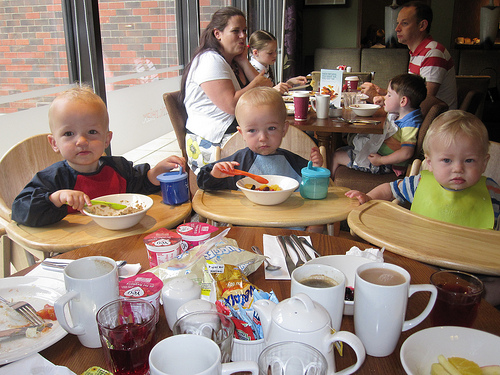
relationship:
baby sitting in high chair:
[10, 81, 189, 231] [0, 129, 193, 256]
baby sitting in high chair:
[193, 88, 324, 207] [194, 119, 364, 227]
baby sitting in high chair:
[344, 108, 499, 232] [348, 134, 497, 274]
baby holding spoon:
[193, 88, 324, 207] [213, 165, 274, 184]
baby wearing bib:
[344, 108, 499, 232] [405, 167, 496, 234]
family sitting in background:
[160, 2, 461, 188] [2, 0, 493, 131]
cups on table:
[51, 239, 440, 373] [2, 223, 494, 373]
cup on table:
[52, 251, 119, 351] [2, 223, 494, 373]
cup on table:
[287, 257, 348, 339] [2, 223, 494, 373]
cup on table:
[352, 262, 437, 358] [2, 223, 494, 373]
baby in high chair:
[10, 81, 189, 231] [0, 129, 193, 256]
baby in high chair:
[193, 88, 324, 207] [194, 119, 364, 227]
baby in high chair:
[344, 108, 499, 232] [348, 134, 497, 274]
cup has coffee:
[287, 257, 348, 339] [297, 274, 337, 288]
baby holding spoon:
[193, 88, 324, 207] [218, 166, 271, 186]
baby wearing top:
[10, 81, 189, 231] [11, 153, 152, 232]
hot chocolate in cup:
[362, 263, 402, 285] [352, 256, 438, 358]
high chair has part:
[194, 119, 364, 227] [195, 185, 350, 227]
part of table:
[333, 115, 347, 131] [267, 55, 411, 146]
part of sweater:
[192, 96, 215, 123] [177, 45, 248, 147]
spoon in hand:
[221, 159, 279, 190] [214, 154, 244, 187]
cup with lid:
[300, 163, 331, 201] [302, 157, 332, 181]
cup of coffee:
[350, 255, 437, 371] [364, 264, 399, 285]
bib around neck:
[404, 165, 497, 240] [416, 174, 487, 203]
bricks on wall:
[123, 19, 155, 57] [5, 5, 235, 141]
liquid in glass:
[106, 332, 143, 367] [92, 294, 161, 371]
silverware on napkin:
[268, 224, 328, 277] [255, 226, 325, 289]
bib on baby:
[409, 165, 495, 231] [344, 107, 499, 242]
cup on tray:
[295, 163, 345, 204] [194, 174, 358, 234]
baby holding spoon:
[193, 88, 324, 207] [223, 162, 269, 187]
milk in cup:
[303, 181, 327, 200] [298, 157, 333, 204]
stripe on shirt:
[397, 173, 412, 199] [389, 165, 498, 234]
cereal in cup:
[138, 225, 196, 269] [138, 218, 182, 262]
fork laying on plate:
[3, 287, 45, 340] [4, 265, 84, 367]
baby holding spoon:
[7, 81, 189, 231] [81, 188, 133, 211]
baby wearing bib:
[344, 107, 499, 242] [406, 169, 498, 244]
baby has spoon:
[193, 88, 324, 207] [215, 161, 266, 187]